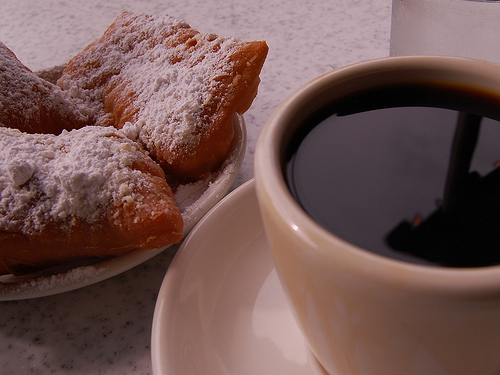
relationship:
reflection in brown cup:
[375, 97, 497, 272] [250, 54, 500, 374]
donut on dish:
[57, 10, 269, 180] [0, 56, 245, 302]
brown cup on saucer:
[250, 54, 500, 374] [166, 195, 315, 372]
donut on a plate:
[1, 123, 183, 265] [7, 169, 247, 326]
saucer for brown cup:
[149, 161, 498, 373] [250, 54, 500, 374]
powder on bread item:
[103, 37, 193, 142] [51, 21, 230, 182]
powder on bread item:
[103, 37, 193, 142] [1, 118, 187, 266]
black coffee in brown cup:
[276, 77, 500, 268] [250, 54, 500, 374]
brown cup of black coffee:
[250, 54, 500, 374] [276, 77, 500, 268]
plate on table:
[131, 174, 323, 374] [1, 0, 391, 373]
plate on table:
[131, 178, 323, 375] [200, 2, 385, 91]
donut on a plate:
[55, 10, 268, 180] [5, 70, 243, 300]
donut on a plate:
[1, 123, 183, 260] [5, 70, 243, 300]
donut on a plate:
[1, 42, 93, 123] [5, 70, 243, 300]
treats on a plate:
[0, 33, 260, 235] [1, 114, 261, 310]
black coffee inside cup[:
[276, 77, 500, 268] [248, 54, 495, 372]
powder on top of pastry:
[0, 123, 150, 235] [1, 9, 266, 254]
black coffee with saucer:
[276, 77, 500, 268] [149, 161, 498, 373]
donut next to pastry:
[57, 10, 269, 180] [3, 123, 179, 251]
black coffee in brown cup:
[278, 72, 498, 277] [270, 201, 498, 356]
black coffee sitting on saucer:
[276, 77, 500, 268] [150, 177, 331, 372]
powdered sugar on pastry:
[57, 152, 99, 188] [83, 188, 176, 250]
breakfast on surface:
[0, 9, 498, 374] [4, 0, 397, 368]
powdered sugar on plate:
[0, 11, 242, 296] [1, 114, 261, 310]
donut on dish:
[57, 10, 269, 180] [0, 50, 252, 309]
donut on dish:
[1, 123, 183, 265] [0, 50, 252, 309]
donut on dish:
[0, 38, 94, 132] [0, 50, 252, 309]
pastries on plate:
[0, 0, 266, 292] [5, 70, 243, 300]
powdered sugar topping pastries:
[0, 11, 242, 296] [0, 10, 267, 300]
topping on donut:
[2, 124, 135, 224] [1, 123, 183, 265]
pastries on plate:
[10, 40, 277, 282] [0, 58, 266, 336]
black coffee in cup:
[276, 77, 500, 268] [224, 39, 496, 352]